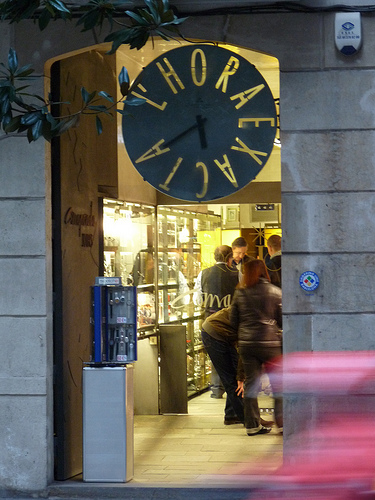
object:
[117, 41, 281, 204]
clock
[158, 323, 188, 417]
door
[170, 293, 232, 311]
writing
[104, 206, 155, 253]
window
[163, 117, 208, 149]
hand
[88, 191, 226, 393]
display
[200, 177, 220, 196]
ground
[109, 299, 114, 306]
watches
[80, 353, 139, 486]
stand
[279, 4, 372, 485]
wall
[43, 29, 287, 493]
entry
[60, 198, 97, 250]
sign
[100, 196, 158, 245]
lights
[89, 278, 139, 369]
case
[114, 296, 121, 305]
watch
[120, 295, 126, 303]
watch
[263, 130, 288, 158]
ground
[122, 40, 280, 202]
sign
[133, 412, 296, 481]
ground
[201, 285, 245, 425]
person bending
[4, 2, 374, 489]
building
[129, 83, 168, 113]
letters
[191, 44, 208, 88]
letters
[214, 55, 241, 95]
letters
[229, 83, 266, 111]
letters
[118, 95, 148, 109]
leaves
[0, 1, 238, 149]
tree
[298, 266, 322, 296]
sign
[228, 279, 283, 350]
jacket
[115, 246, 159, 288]
doors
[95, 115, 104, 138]
leaves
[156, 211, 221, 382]
glass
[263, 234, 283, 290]
person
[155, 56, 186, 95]
letter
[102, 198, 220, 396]
display cases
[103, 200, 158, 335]
glass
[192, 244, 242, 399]
man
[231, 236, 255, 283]
man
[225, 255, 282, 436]
girl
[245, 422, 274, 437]
shoe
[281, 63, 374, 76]
line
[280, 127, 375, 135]
line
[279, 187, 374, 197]
line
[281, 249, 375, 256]
line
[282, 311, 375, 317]
line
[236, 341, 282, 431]
pants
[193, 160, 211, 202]
word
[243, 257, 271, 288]
hair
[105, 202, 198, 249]
items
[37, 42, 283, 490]
store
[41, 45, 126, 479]
door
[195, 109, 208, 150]
hands